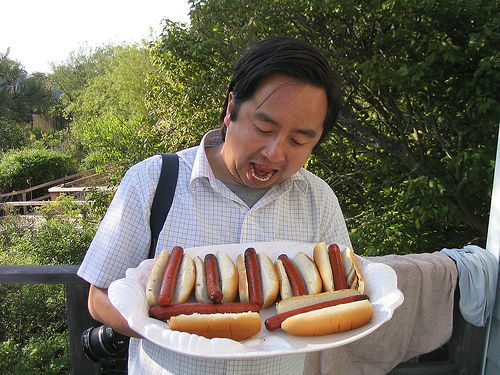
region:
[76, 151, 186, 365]
Black camera strapped over a shoulder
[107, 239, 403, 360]
Decorative white serving tray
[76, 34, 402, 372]
Man holding a tray of hotdogs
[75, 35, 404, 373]
Man getting ready to eat seven hot dogs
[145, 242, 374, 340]
Seven plain hot dogs in buns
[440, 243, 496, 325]
Underwear hanging off a balcony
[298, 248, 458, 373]
Gray bath towel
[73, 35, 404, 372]
Man looking at a plate of hot dogs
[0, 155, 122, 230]
Light wood boardwalk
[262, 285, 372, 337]
Hot dog in a white bun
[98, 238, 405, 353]
plate of hotdogs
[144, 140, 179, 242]
strap of the camera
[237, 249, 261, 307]
hotdog on a bun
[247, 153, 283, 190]
mouth open on the guy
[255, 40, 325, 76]
black hair on the guy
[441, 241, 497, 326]
clothing on the rail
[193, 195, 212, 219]
white checkered shirt on the man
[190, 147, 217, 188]
collar of the shirt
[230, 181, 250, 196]
gray shirt on the man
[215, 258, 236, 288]
bun of the hotdog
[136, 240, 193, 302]
hot dog on the platter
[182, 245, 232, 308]
hot dog on the platter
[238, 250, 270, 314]
hot dog on the platter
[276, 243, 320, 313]
hot dog on the platter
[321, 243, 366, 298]
hot dog on the platter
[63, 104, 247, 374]
man is carrying a camera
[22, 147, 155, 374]
man is carrying a camera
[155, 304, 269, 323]
Hotdog on a bun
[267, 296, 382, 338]
Hotdog on a bun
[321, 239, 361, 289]
Hotdog on a bun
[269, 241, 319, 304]
Hotdog on a bun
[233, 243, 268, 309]
Hotdog on a bun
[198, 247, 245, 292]
Hotdog on a bun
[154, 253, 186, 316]
Hotdog on a bun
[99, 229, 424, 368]
Several hot dogs on a plate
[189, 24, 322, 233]
Man making a strange face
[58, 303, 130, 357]
Black camera in a person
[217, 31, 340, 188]
Man with black hair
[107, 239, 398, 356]
Seven grilled hot dogs on buns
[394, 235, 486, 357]
Clothing hanging over balcony rail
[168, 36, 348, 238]
Man wearing white shirt with plaid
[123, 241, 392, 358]
Large white serving tray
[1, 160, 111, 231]
Steps with wooden railings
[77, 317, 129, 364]
Camera hanging from man's shoulder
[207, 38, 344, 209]
Man wearing gray undershirt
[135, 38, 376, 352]
Man holding tray of hot dogs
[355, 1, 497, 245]
Green tree next to balcony